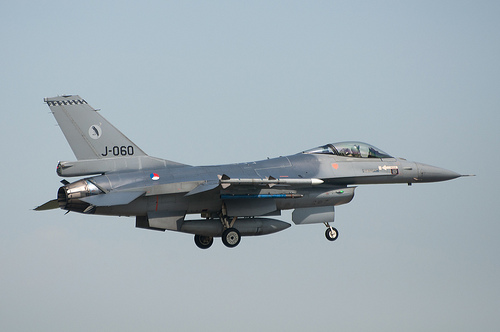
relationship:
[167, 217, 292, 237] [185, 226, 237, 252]
missile between wheels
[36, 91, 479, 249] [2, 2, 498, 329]
fighter jet flying in sky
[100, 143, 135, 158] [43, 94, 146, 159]
id on tail wing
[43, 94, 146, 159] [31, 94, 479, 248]
tail wing on fighter jet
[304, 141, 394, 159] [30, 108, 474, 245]
window on jet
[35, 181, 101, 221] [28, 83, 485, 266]
engine on jet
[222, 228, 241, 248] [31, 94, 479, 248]
wheel on fighter jet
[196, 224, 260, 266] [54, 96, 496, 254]
wheel on jet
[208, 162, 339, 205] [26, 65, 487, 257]
missile on jet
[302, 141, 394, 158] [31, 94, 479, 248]
cockpit of fighter jet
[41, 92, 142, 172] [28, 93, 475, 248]
tail of jetplane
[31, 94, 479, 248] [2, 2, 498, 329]
fighter jet in sky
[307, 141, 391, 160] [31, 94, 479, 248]
window of fighter jet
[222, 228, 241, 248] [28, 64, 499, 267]
wheel of plane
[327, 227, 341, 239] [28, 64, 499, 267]
wheel of plane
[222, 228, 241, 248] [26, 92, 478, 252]
wheel of plane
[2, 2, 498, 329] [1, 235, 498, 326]
sky has cloud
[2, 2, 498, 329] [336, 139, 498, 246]
sky has cloud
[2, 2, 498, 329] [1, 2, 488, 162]
sky has cloud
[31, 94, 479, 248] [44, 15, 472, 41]
fighter jet in air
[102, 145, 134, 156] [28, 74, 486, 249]
id on plane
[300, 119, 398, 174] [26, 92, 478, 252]
pilot in plane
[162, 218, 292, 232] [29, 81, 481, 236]
missile on bottom plane